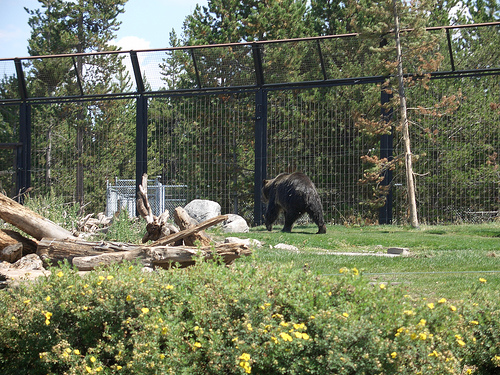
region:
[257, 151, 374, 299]
a black bear in a field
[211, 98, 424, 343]
a bear walking on all fours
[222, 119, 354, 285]
a black bear walking on all fours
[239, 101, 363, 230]
bear in a fenced in area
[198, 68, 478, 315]
a tall metal fence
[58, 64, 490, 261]
a tall black fence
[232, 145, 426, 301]
a bear in a field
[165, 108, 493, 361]
an area with a bear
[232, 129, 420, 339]
an area with a black bear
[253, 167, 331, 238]
bear in the enclosure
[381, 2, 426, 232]
tree growing by the fence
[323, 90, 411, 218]
fence in the enclosure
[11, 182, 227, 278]
logs laying on the ground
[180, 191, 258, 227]
large rocks by the fence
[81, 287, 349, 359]
weeds growing in the enclosure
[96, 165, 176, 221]
silver fence behind the enclosure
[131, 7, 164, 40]
powder blue sky above the trees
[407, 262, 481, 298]
grass covering the ground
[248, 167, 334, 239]
bear is walking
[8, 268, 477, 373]
a bush in front of the bear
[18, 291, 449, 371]
yellow flowers on the bush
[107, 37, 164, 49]
a cloud in the sky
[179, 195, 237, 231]
boulders on the ground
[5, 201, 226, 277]
a pile of logs on the grass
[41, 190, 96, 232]
tall grass behind the logs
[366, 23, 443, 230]
a tree next to the bear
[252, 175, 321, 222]
a bear walking toward the fence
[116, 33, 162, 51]
a cloud in the sky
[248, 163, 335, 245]
bear is color black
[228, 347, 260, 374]
the yellow flowers in a bush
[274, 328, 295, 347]
the yellow flowers in a bush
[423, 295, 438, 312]
the yellow flowers in a bush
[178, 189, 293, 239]
rocks near a bear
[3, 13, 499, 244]
a fence in front of bear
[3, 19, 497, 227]
the fence is black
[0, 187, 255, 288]
the log on a field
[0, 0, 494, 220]
trees behind the fence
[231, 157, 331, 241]
bear walks toward the fence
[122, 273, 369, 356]
YELLOW FLOWERS IN BUSHES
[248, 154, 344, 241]
BLACK BEAR IN ZOO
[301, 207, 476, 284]
GREEN GRASS UNDER BEAR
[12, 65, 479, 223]
TALL FENCE AROUND ZOO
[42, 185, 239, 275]
DEAD LOGS ON GROUND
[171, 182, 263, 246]
LARGE ROCKS BY BEAR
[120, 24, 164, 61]
WHITE CLOUDS IN SKY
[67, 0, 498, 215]
TALL TREES PASSED FENCE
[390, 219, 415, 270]
SMALL STEP ON GROUND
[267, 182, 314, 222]
BLACK FUR OF BEAR